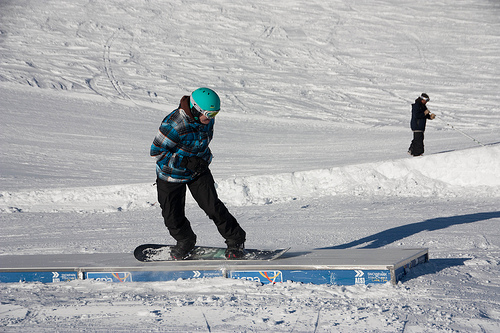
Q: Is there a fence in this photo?
A: No, there are no fences.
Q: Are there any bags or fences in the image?
A: No, there are no fences or bags.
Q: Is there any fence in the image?
A: No, there are no fences.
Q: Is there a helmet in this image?
A: Yes, there is a helmet.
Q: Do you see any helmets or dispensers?
A: Yes, there is a helmet.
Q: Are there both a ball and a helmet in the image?
A: No, there is a helmet but no balls.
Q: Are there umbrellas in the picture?
A: No, there are no umbrellas.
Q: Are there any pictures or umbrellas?
A: No, there are no umbrellas or pictures.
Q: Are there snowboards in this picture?
A: Yes, there is a snowboard.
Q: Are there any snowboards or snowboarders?
A: Yes, there is a snowboard.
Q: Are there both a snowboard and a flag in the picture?
A: No, there is a snowboard but no flags.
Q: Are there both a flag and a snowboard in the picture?
A: No, there is a snowboard but no flags.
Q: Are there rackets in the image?
A: No, there are no rackets.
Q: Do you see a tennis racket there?
A: No, there are no rackets.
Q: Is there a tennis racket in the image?
A: No, there are no rackets.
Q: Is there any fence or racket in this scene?
A: No, there are no rackets or fences.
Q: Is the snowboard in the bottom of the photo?
A: Yes, the snowboard is in the bottom of the image.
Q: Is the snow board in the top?
A: No, the snow board is in the bottom of the image.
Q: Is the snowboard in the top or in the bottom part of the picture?
A: The snowboard is in the bottom of the image.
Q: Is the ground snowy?
A: Yes, the ground is snowy.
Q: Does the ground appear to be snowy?
A: Yes, the ground is snowy.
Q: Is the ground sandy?
A: No, the ground is snowy.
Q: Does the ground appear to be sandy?
A: No, the ground is snowy.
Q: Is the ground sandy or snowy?
A: The ground is snowy.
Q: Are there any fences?
A: No, there are no fences.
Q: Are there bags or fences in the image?
A: No, there are no fences or bags.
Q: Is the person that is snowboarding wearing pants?
A: Yes, the person is wearing pants.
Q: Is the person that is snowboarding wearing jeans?
A: No, the person is wearing pants.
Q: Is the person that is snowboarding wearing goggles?
A: Yes, the person is wearing goggles.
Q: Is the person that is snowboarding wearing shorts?
A: No, the person is wearing goggles.